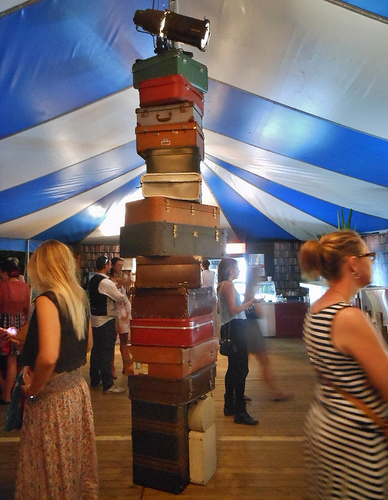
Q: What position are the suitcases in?
A: Stacked.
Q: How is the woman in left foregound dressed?
A: Shirt and skirt.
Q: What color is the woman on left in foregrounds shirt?
A: Black.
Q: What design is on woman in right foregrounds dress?
A: Stripes.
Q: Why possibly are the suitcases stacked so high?
A: To hold light.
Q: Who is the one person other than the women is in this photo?
A: Man.